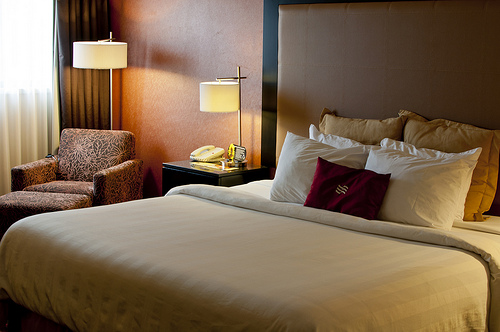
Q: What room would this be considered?
A: Bedroom.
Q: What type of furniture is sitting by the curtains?
A: A chair.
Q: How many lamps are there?
A: 2.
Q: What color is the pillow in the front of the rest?
A: Red.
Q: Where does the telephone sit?
A: On the nightstand.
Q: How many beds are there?
A: 1.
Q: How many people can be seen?
A: None.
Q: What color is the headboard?
A: Brown.